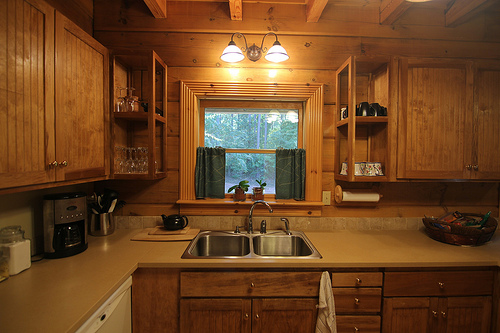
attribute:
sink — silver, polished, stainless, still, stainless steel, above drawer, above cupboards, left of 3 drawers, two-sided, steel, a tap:
[182, 201, 321, 259]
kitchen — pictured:
[2, 2, 500, 332]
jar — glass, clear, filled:
[2, 223, 32, 278]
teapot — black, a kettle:
[160, 211, 189, 230]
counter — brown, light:
[2, 217, 500, 332]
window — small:
[197, 98, 309, 203]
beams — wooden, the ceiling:
[142, 1, 490, 26]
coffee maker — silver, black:
[35, 191, 89, 258]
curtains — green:
[194, 147, 305, 199]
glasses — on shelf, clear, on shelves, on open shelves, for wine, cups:
[115, 144, 159, 175]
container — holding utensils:
[89, 207, 114, 235]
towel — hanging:
[316, 270, 336, 331]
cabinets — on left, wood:
[2, 3, 113, 195]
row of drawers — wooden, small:
[328, 268, 383, 332]